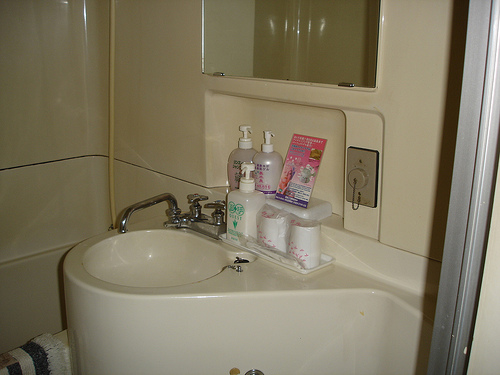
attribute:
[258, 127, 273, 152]
pump — white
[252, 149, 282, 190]
bottle — clear, plastic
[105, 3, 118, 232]
hose — skinny, off white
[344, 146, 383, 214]
outlet — silver, covered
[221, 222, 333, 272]
tray — white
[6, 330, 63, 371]
bath mat — white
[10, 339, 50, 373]
stripes — blue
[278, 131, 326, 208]
package — pink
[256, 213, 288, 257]
cup — plastic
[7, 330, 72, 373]
towel — blue, white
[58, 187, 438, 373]
sink — small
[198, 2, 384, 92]
mirror — clean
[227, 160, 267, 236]
bottle — lotion, hand soap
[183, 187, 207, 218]
handle — metal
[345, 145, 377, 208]
socket — covered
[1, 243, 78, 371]
tub — empty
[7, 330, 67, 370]
towel — blue, white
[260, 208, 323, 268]
cups — plastic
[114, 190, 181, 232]
faucet — silver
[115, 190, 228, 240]
faucet — silver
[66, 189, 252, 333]
sink — Circular 